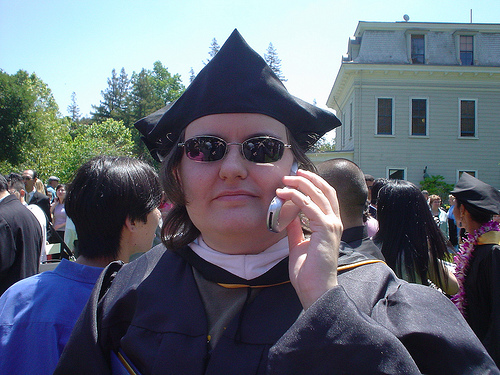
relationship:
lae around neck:
[449, 225, 497, 304] [460, 221, 497, 242]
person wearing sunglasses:
[52, 23, 500, 375] [175, 140, 301, 164]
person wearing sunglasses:
[120, 60, 385, 267] [168, 120, 308, 186]